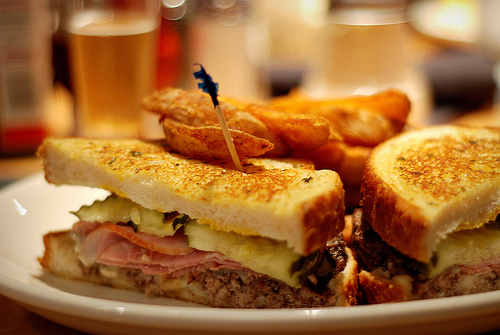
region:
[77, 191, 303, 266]
The pickles are on the sandwich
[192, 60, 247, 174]
A toothpick is in the sandwich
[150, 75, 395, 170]
French fries are behind the sandwich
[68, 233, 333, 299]
The meat is between the bread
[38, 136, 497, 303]
The sandwich is on the plate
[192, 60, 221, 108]
Top of the toothpick is blue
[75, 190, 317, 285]
The pickles are green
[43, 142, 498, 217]
The bread is toasted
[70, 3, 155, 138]
A glass is behind the plate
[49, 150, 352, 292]
sandwich on the plate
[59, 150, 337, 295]
sandwich on the plate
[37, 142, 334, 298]
sandwich on the plate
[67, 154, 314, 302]
sandwich on the plate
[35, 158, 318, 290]
sandwich on the plate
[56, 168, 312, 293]
sandwich on the plate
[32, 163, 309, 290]
sandwich on the plate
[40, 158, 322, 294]
sandwich on the plate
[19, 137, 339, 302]
sandwich on the plate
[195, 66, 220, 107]
The blue part of the toothpick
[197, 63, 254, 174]
The tooth pick in the sandwhich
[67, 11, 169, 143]
A beer in the background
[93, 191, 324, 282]
The pickle that is on the sandwhich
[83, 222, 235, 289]
The meat that is on the sandwhich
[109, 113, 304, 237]
The top toast of the sandwhich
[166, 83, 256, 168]
The french fries touching the sandwhich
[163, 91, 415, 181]
The french fries behind the sandwhich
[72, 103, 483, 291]
A sandwhich that is cut in half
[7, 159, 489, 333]
A white plate with a sand which on it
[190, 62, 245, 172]
A small wooden toothpick in the sandwich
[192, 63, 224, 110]
A small amount of blue plastic on the tip of the toothpick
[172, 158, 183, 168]
A small fleck of pepper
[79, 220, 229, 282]
A few slices of pink ham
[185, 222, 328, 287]
Two slices of green pickle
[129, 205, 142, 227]
A pickle seed on the small pickle slice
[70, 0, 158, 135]
A beverage behind the sandwich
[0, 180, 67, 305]
A white plate under the sandwich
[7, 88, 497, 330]
A sandwich and fries on a white plate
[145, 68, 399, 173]
Golden french fries by the sandwich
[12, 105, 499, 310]
this is a sandwich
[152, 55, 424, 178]
these are fries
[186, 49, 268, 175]
this is a toothpick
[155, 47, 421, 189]
these are fried potatoes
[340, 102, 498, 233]
the bread is buttered and toasted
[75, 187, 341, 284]
these are slices of pickle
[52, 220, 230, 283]
this is sliced ham and turkey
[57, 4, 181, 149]
a glass of beer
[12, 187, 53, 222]
reflection of light on the plate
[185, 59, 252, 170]
toothpick on top of the sandwich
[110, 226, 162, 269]
meat inside the sandwich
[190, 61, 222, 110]
top of the toothpick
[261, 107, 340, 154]
french fries on the plate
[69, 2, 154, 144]
the beer is in the glass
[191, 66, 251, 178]
the toothpick in sandwich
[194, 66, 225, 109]
blue plastic is on toothpick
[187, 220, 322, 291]
the pickle is green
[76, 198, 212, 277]
pickle is above the ham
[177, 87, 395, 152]
the potatoes are brown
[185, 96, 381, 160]
the wedges are seasoned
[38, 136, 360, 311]
large half cut sandwich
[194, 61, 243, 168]
small thin tooth pick